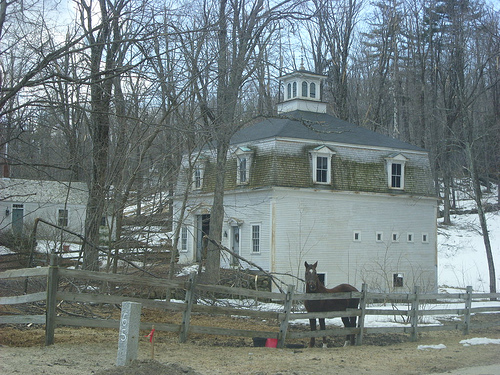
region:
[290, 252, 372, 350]
the horse is standing next to a fence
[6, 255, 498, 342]
the fence is made of wood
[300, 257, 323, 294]
the horse has a star on its head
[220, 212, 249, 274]
the front door of the house has a wreath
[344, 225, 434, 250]
small windows are on the side of the house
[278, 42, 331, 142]
the house has a cupola on top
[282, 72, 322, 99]
arched windows under the cupola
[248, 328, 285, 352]
buckets are near the horse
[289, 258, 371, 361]
horse near wooden fence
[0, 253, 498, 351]
wooden fence with railing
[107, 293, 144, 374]
marker with number '65' painted on it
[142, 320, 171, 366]
red marker with post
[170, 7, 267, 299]
deciduous tree with no leaves on it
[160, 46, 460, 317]
barn or home old style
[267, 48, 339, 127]
steeple on top of building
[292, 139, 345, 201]
side windows on building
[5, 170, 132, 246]
structure with doors and windows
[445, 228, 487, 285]
white snow on hill behind building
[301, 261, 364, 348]
Brown horse in front of fence.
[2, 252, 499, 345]
Wooden fence in front of horse.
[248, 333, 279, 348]
black and red buckets.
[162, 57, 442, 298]
building behind the horse.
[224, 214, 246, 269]
door on the building.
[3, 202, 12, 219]
Light on the side of the building.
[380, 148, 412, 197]
window in the structure.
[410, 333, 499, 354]
snow on the ground.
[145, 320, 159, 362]
Red flag on stick.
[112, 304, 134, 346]
Number on the post.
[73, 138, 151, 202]
branch of the tree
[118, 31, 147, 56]
branch of the tree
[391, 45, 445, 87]
branch of the tree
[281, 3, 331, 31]
branch of the tree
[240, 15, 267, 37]
branch of the tree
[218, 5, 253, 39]
branch of the tree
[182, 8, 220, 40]
branch of the tree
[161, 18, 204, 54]
branch of the tree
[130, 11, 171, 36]
branch of the tree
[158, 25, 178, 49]
branch of the tree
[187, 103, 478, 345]
white and brown house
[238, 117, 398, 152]
grey roof of building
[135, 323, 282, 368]
red flags outside fence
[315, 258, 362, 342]
brown horse near fence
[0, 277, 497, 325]
grey and wooden fence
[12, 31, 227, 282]
bare trees around building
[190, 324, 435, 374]
brown grass on ground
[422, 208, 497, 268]
white snow behind building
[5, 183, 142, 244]
white building in trees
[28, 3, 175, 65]
blue and white sky